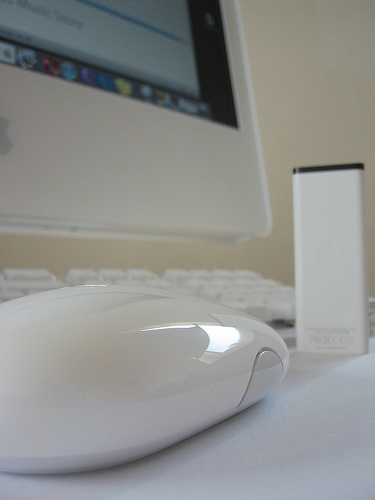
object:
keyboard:
[0, 267, 296, 323]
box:
[292, 163, 368, 355]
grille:
[0, 221, 240, 246]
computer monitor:
[0, 0, 271, 243]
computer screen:
[0, 0, 237, 133]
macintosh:
[306, 327, 357, 349]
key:
[214, 270, 234, 278]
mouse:
[0, 283, 287, 472]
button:
[236, 348, 284, 408]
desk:
[0, 332, 374, 500]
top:
[292, 163, 363, 176]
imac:
[0, 0, 368, 350]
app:
[60, 62, 78, 82]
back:
[292, 168, 362, 356]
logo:
[0, 118, 13, 160]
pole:
[292, 165, 304, 351]